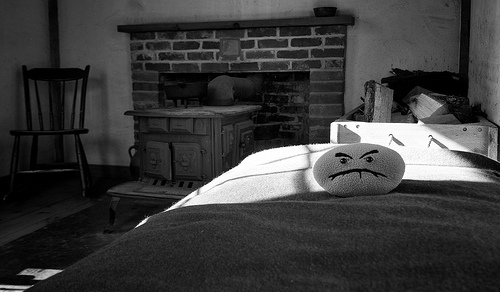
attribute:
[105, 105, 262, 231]
dresser — wooden, brown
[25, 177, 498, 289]
sheet — dark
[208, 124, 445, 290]
sheets — wool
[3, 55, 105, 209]
chair — brown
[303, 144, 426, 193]
face — frowny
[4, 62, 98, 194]
chair — brown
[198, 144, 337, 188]
sheet — white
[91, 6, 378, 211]
fire place — brick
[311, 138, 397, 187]
face — grumpy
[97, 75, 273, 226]
stove — wooden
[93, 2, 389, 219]
fireplace — brick